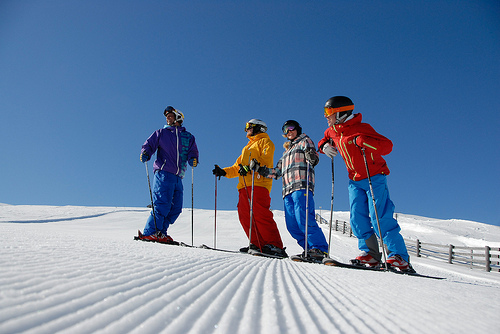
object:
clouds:
[63, 0, 470, 87]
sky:
[51, 11, 95, 119]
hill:
[75, 262, 262, 315]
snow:
[35, 207, 94, 248]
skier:
[274, 107, 331, 265]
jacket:
[141, 125, 200, 179]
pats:
[235, 186, 281, 261]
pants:
[347, 173, 409, 262]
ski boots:
[237, 241, 289, 256]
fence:
[427, 244, 500, 273]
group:
[133, 95, 446, 281]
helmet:
[324, 96, 355, 124]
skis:
[133, 232, 190, 251]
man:
[212, 119, 288, 260]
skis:
[200, 244, 288, 259]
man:
[260, 119, 328, 262]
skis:
[287, 253, 326, 267]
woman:
[316, 95, 418, 275]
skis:
[322, 258, 444, 280]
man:
[318, 95, 417, 276]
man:
[132, 102, 201, 244]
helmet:
[162, 105, 184, 124]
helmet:
[282, 119, 302, 136]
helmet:
[245, 118, 268, 136]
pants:
[143, 170, 183, 236]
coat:
[268, 132, 320, 199]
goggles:
[324, 105, 355, 118]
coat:
[318, 113, 394, 182]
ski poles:
[191, 166, 193, 250]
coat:
[222, 133, 274, 193]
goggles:
[282, 125, 295, 134]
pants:
[236, 186, 283, 249]